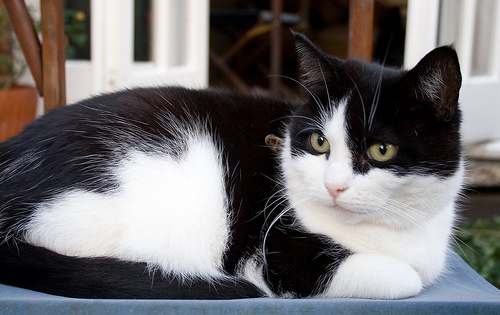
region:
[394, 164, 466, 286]
soft white hair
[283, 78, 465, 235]
black and white cat face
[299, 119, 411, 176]
yellow and black cat eyes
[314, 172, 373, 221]
pink cat nose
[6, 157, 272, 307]
black cat tail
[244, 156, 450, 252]
white whiskers on cat face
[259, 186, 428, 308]
black and white cat paw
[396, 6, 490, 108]
black cat ear with hairs inside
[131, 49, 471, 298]
calm cat resting on blue chair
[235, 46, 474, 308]
curious cat looking to the distance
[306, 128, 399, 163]
Eyes of a black and white cat.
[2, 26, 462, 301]
Black and white cat who is lying down.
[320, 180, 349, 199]
Small pink tip of a cats nose.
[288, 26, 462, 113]
Black ears of a black and white cat.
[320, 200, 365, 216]
Mouth of a black and white cat.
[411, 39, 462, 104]
A cats left ear.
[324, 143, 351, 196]
Nose of a black and white cat.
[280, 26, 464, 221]
Head of a black and white cat.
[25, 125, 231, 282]
Large white patch of fur on a cats hind quarters.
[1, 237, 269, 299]
Solid black tail of a cat lying down.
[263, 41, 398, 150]
Top white whiskers on a black and white cats face.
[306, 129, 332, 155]
A cats right eyeball.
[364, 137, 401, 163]
A cat left eyeball.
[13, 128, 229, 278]
Large white fur patch on a cats back hind quarter.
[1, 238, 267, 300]
Solid black tail of a cat.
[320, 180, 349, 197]
Small pink end of a cats nose.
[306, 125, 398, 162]
Lime green colored cats eyes.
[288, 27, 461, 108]
Black ears with white hairs coming out on a cats head.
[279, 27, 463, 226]
Black and white cats head with a pink nose.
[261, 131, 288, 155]
Little end of a cats collar sticking out on the left of its head.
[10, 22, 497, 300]
black and white cat curled up on a blue mat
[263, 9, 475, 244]
head of a black and white cat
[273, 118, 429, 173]
yellow eyes of a black and white cat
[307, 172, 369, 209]
pink nose of a cat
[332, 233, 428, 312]
white paw of a cat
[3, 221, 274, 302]
black tail of a cat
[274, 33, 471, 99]
black ears of a cat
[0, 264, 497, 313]
blue blanket underneath a cat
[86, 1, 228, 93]
white doors with a window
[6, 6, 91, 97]
wooden beams in front of a white wall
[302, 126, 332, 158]
Yellow and black cat eye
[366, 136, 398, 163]
Yellow and black cat eye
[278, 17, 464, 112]
Black and white cat ears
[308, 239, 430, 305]
White cat paw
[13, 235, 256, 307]
Black cat tail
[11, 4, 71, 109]
Medium brown tree trunks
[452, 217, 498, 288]
Green foliage on the ground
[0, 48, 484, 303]
Black and white cat laying down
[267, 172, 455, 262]
White cat mouth and whiskers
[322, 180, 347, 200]
Small pink nose